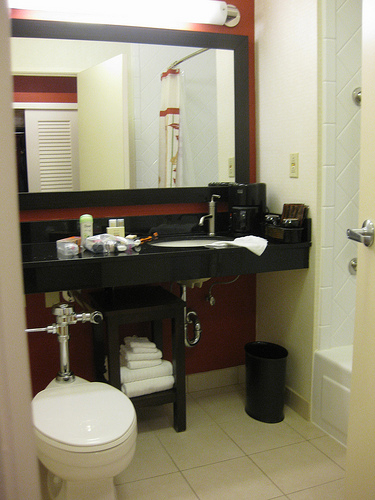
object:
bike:
[136, 214, 179, 262]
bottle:
[106, 218, 125, 238]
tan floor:
[112, 384, 349, 500]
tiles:
[113, 379, 344, 500]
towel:
[205, 235, 269, 257]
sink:
[150, 240, 230, 248]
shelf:
[103, 335, 175, 398]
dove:
[80, 213, 93, 248]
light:
[6, 0, 241, 29]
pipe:
[180, 284, 203, 348]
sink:
[148, 239, 235, 248]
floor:
[112, 375, 349, 500]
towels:
[103, 334, 175, 398]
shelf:
[83, 284, 187, 433]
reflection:
[159, 67, 197, 190]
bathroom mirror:
[10, 37, 237, 194]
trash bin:
[244, 341, 289, 425]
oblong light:
[0, 0, 243, 25]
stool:
[87, 282, 187, 432]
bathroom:
[0, 0, 373, 498]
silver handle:
[346, 220, 375, 248]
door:
[344, 0, 374, 500]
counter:
[20, 225, 310, 293]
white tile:
[323, 46, 353, 137]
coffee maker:
[227, 182, 266, 237]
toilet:
[31, 368, 137, 500]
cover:
[6, 0, 227, 24]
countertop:
[21, 227, 308, 296]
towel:
[124, 335, 157, 348]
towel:
[125, 343, 157, 354]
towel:
[119, 343, 163, 361]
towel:
[119, 356, 163, 370]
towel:
[103, 356, 173, 385]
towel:
[103, 370, 176, 399]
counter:
[20, 229, 311, 294]